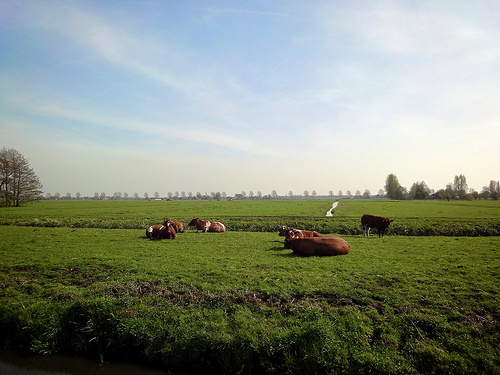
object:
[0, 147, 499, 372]
plants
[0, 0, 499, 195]
cloud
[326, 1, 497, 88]
cloud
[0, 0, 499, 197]
sky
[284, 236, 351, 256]
animal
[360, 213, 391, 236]
animal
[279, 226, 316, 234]
animal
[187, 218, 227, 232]
animal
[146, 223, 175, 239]
animal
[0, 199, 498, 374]
grass